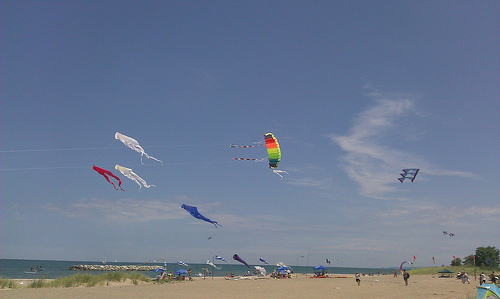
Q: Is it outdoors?
A: Yes, it is outdoors.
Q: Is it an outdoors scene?
A: Yes, it is outdoors.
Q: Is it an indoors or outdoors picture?
A: It is outdoors.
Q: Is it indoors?
A: No, it is outdoors.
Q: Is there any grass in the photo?
A: Yes, there is grass.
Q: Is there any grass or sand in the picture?
A: Yes, there is grass.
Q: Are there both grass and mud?
A: No, there is grass but no mud.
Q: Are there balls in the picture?
A: No, there are no balls.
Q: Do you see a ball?
A: No, there are no balls.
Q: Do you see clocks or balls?
A: No, there are no balls or clocks.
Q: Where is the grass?
A: The grass is on the beach.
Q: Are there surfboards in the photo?
A: No, there are no surfboards.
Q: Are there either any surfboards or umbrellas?
A: No, there are no surfboards or umbrellas.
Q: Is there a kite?
A: Yes, there is a kite.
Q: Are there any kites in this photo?
A: Yes, there is a kite.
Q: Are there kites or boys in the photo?
A: Yes, there is a kite.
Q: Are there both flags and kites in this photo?
A: No, there is a kite but no flags.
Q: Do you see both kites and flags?
A: No, there is a kite but no flags.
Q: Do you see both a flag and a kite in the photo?
A: No, there is a kite but no flags.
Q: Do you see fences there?
A: No, there are no fences.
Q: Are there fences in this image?
A: No, there are no fences.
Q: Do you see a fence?
A: No, there are no fences.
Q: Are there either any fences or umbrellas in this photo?
A: No, there are no fences or umbrellas.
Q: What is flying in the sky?
A: The kite is flying in the sky.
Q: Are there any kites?
A: Yes, there is a kite.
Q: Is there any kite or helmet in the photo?
A: Yes, there is a kite.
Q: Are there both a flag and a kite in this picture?
A: No, there is a kite but no flags.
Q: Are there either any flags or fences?
A: No, there are no fences or flags.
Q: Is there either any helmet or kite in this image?
A: Yes, there is a kite.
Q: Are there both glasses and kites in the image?
A: No, there is a kite but no glasses.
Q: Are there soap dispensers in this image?
A: No, there are no soap dispensers.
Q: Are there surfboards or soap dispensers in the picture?
A: No, there are no soap dispensers or surfboards.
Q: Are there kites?
A: Yes, there is a kite.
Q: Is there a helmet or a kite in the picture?
A: Yes, there is a kite.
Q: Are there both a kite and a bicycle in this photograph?
A: No, there is a kite but no bicycles.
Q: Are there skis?
A: No, there are no skis.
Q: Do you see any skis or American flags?
A: No, there are no skis or American flags.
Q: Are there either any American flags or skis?
A: No, there are no skis or American flags.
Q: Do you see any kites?
A: Yes, there is a kite.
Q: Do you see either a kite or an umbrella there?
A: Yes, there is a kite.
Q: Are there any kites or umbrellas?
A: Yes, there is a kite.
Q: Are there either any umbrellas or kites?
A: Yes, there is a kite.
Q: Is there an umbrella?
A: No, there are no umbrellas.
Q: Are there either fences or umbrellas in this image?
A: No, there are no umbrellas or fences.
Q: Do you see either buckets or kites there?
A: Yes, there is a kite.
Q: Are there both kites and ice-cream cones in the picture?
A: No, there is a kite but no ice-cream cones.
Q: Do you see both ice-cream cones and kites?
A: No, there is a kite but no ice-cream cones.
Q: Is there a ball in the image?
A: No, there are no balls.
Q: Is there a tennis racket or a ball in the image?
A: No, there are no balls or rackets.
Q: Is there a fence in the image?
A: No, there are no fences.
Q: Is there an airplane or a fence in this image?
A: No, there are no fences or airplanes.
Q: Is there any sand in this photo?
A: Yes, there is sand.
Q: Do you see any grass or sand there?
A: Yes, there is sand.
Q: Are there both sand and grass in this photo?
A: Yes, there are both sand and grass.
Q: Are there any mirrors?
A: No, there are no mirrors.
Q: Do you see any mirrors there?
A: No, there are no mirrors.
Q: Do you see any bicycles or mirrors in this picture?
A: No, there are no mirrors or bicycles.